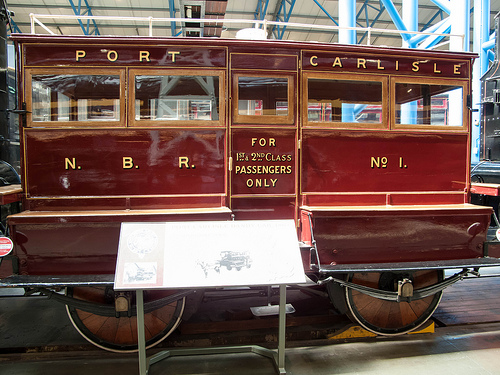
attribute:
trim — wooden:
[20, 63, 474, 133]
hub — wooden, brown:
[348, 271, 441, 331]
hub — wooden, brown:
[71, 285, 180, 345]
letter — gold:
[72, 48, 88, 61]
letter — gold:
[105, 48, 117, 62]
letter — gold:
[166, 49, 179, 63]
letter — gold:
[138, 50, 150, 64]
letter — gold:
[308, 54, 318, 66]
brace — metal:
[35, 287, 195, 317]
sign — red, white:
[1, 230, 16, 259]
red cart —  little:
[473, 182, 498, 212]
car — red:
[13, 35, 472, 215]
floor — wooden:
[430, 275, 499, 322]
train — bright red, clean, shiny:
[9, 24, 486, 227]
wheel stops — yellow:
[331, 320, 447, 338]